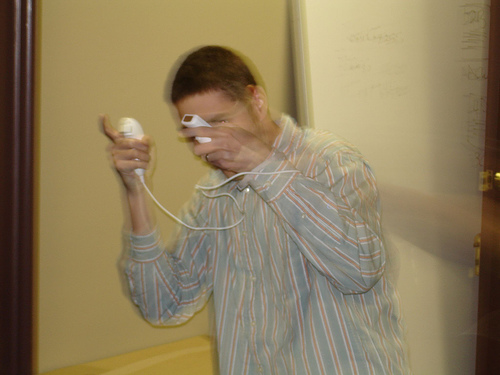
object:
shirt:
[116, 114, 411, 374]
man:
[96, 45, 413, 374]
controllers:
[114, 113, 303, 231]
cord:
[136, 171, 300, 231]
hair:
[171, 45, 257, 106]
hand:
[177, 123, 273, 173]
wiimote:
[180, 113, 213, 144]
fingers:
[176, 120, 233, 168]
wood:
[0, 0, 41, 374]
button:
[244, 188, 250, 193]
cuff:
[236, 149, 300, 202]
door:
[471, 0, 499, 374]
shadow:
[283, 0, 314, 130]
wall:
[36, 0, 299, 375]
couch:
[41, 337, 218, 374]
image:
[0, 0, 499, 375]